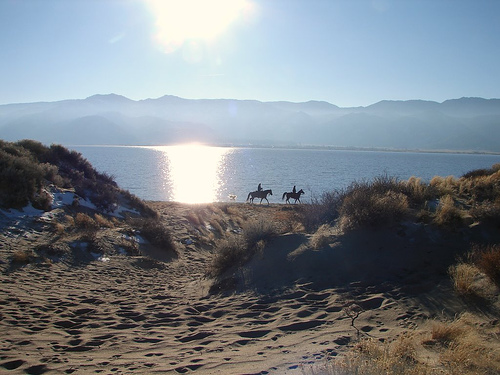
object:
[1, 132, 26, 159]
bushes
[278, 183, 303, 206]
riders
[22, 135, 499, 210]
water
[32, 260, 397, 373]
sand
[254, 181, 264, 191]
person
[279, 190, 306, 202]
horse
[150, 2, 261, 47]
sun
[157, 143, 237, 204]
reflecting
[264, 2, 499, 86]
blue sky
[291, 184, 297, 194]
person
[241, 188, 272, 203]
horse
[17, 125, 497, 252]
shore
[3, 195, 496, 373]
ground